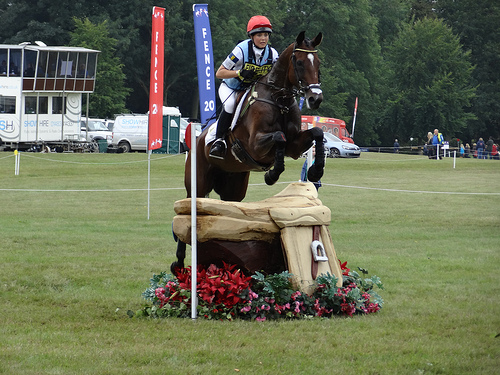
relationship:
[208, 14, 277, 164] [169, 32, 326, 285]
woman on horse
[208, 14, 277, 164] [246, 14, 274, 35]
woman wearing helmet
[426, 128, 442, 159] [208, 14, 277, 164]
people watching woman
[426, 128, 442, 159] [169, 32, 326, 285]
people watching horse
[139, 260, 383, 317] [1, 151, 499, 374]
flowers on grass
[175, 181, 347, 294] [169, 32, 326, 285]
complex under horse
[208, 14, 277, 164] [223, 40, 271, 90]
woman wearing vest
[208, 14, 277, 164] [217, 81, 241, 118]
woman wearing pants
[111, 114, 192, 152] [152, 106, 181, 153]
van behind potty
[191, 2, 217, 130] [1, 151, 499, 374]
sign on grass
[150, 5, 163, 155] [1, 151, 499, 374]
sign on grass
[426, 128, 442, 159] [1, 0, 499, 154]
people by trees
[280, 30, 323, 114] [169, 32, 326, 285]
head on horse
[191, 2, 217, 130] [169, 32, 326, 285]
sign by horse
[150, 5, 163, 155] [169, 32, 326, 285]
sign by horse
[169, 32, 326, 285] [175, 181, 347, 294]
horse over complex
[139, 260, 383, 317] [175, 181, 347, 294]
flowers by complex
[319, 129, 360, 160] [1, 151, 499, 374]
car on grass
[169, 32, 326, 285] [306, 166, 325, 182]
horse has hoove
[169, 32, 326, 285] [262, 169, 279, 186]
horse has hoove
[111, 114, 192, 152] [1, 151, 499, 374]
van on grass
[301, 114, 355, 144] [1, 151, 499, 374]
suv on grass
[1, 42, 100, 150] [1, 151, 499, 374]
building by grass